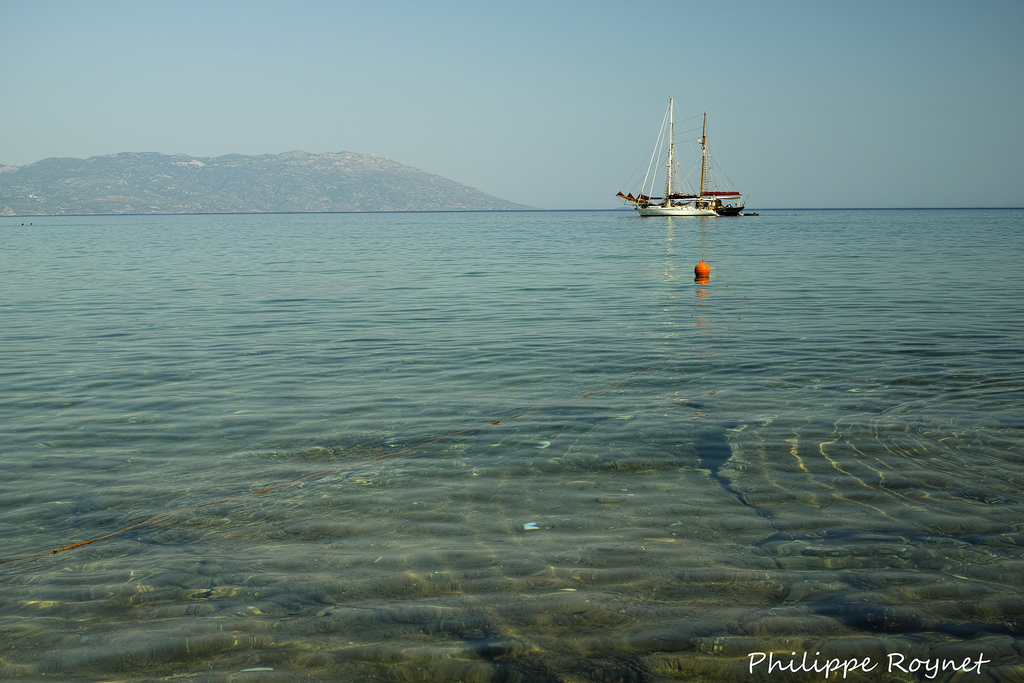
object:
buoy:
[695, 258, 711, 280]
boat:
[616, 96, 759, 216]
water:
[0, 207, 1024, 683]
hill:
[0, 151, 537, 215]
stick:
[0, 285, 748, 566]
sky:
[0, 0, 1024, 218]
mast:
[640, 95, 675, 202]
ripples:
[0, 379, 1022, 680]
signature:
[745, 651, 991, 679]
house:
[172, 159, 207, 166]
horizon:
[0, 207, 1024, 218]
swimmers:
[788, 213, 797, 215]